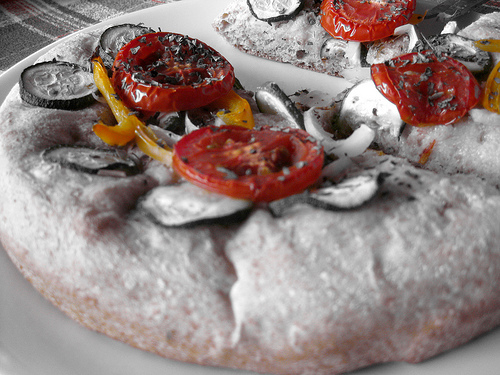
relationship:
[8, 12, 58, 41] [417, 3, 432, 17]
cloth placed at table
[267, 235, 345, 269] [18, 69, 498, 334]
white sprinkled on bread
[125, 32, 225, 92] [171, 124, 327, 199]
basil on top of tomato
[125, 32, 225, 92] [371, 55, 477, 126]
basil on top of tomato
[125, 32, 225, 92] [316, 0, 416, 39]
basil on top of tomato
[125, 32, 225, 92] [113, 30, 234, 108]
basil on top of tomato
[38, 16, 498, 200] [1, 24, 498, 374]
veggies on top of bread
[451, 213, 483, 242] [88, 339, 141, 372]
bread on plate.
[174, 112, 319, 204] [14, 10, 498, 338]
tomato on top of food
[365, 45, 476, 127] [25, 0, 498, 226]
tomato on top of food